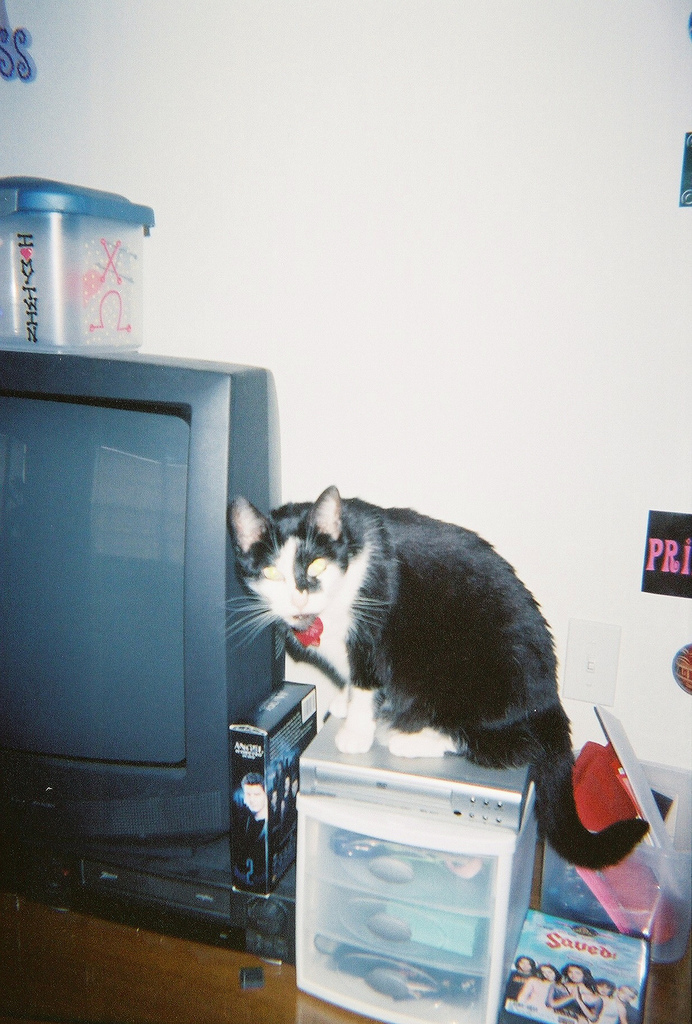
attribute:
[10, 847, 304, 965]
vcr — black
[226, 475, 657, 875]
cat — black, white, domestic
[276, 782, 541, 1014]
drawers — white, clear, small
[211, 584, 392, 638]
whiskers — white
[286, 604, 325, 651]
tag — red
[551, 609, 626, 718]
jack — white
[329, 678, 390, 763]
paw — white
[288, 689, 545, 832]
dvd player — silver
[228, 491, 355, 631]
face — white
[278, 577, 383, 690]
chest — white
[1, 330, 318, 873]
television — old fashion, tube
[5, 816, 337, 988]
vhs player — black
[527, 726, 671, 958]
container — transparent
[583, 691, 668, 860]
lid — open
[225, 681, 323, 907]
box — original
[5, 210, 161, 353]
storage container — plastic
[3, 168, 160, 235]
lid — blue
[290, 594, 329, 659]
collar — red